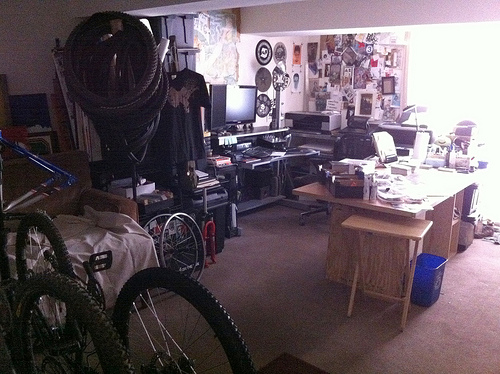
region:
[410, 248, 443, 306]
A blue recycling trash can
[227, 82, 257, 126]
A computer monitor on a desk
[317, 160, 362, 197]
A black tray on a desk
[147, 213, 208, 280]
Tire rims for bicycles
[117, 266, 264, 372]
Black bike tires in a room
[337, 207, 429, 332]
Light colored TV tray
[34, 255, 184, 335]
these are bicycles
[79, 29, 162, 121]
these tires are hanging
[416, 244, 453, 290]
this is a recycling bin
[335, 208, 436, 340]
small wooden tray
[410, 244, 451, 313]
blue plastic basket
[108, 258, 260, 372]
black rubber bicycle wheel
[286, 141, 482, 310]
tan wooden desk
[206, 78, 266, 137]
black computer monitor on desk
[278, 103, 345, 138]
black and silver printer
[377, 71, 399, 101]
picture on wall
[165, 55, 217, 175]
black t-shirt handing on wall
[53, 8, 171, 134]
row of bicycle tires hanging on wall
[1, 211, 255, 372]
bicycle is upside down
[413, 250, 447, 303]
blue waste basket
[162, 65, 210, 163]
black shirt hanging up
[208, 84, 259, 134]
two computer monitors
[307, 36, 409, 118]
wall is very cluttered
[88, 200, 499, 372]
carpet is beige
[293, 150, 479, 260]
the counter is cluttered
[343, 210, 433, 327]
wooden table used while watching tv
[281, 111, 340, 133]
printer next to the wall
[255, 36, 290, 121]
round pictures hanging on the wall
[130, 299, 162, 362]
metal spoke on tire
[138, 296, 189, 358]
metal spoke on tire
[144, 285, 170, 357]
metal spoke on tire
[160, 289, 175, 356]
metal spoke on tire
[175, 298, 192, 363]
metal spoke on tire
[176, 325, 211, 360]
metal spoke on tire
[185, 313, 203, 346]
metal spoke on tire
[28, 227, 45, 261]
metal spoke on tire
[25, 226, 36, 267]
metal spoke on tire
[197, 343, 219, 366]
metal spoke on tire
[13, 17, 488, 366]
wooden table surrounded by storage and bicycle parts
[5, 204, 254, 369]
textures black tires with metal spokes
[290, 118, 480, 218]
tabletop filled with rectangular and square items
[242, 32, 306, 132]
wall covered with circles and faces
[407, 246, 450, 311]
blue trash can on floor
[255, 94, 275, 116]
A sign on a wall.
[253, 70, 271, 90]
A sign on a wall.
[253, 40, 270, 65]
A sign on a wall.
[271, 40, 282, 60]
A sign on a wall.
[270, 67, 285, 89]
A sign on a wall.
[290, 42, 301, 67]
A sign on a wall.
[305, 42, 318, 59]
A sign on a wall.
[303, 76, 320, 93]
A sign on a wall.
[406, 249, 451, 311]
blue plastic waste basket